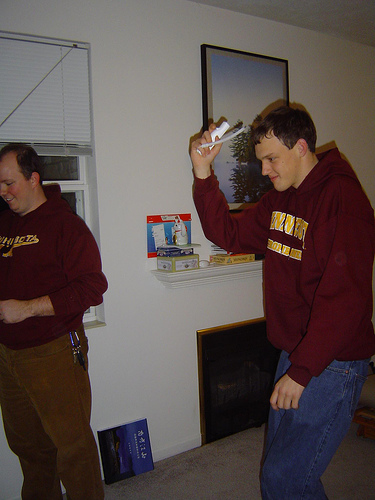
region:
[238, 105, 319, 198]
head of a person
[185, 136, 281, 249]
arm of a person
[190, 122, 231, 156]
hand of a person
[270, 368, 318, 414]
hand of a person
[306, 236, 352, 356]
arm of a person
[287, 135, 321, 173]
ear of a person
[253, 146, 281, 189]
eye of a person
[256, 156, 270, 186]
nose of a person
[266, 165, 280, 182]
mouth of a person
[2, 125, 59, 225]
head of a person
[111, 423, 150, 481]
BOOK ON THE WALL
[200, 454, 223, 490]
CARPET ON THE FLOOR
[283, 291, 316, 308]
MAN WEARING BURGANDY SWEATER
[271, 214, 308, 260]
YELLOW LOGO ON THE SWEATER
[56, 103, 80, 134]
BLINDS AT THE WINDOW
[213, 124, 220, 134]
REMOTE IN MAN HAND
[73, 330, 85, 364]
KEYS ON THE HIP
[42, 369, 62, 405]
MAN WEARING BROWN PANTS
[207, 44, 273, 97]
PICTURE ON THE WALL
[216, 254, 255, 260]
BOOK ON TOP OF FIRE PLACE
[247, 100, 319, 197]
the head of a man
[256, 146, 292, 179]
the eye of a man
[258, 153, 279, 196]
the nose of a man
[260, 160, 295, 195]
the mouth of a man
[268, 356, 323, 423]
the hand of a man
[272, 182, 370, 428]
the arm of a man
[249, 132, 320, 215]
the ear of a man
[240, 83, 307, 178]
the forehead of a man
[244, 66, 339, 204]
the hair of a man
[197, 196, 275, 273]
the elbow of a man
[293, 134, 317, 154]
ear of a person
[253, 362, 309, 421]
hand of a person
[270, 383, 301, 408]
finger of a person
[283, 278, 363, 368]
arm of a person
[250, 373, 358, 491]
leg of a person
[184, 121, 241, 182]
hand of a person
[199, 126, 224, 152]
finger of a person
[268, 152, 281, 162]
eye of a person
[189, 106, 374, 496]
a young man playing video game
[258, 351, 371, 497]
a pair of blue jeans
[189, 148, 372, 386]
a red printed sweatshirt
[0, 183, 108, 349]
a red printed sweatshirt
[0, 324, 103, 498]
a pair of brown pants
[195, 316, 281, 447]
a built in fireplace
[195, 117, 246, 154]
a Wii game controller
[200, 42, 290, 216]
a framed print on wall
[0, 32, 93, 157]
a set of white venetian blinds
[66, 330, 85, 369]
a key ring with keys